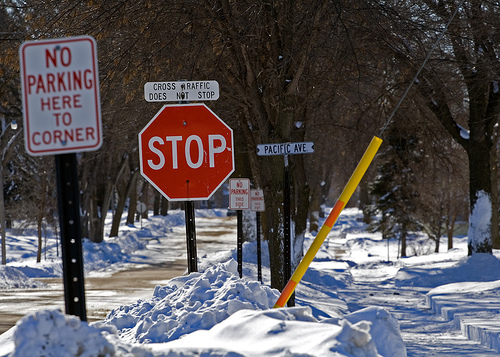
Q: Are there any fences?
A: No, there are no fences.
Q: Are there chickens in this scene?
A: No, there are no chickens.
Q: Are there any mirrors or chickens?
A: No, there are no chickens or mirrors.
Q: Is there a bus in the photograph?
A: No, there are no buses.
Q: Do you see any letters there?
A: Yes, there are letters.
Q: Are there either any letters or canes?
A: Yes, there are letters.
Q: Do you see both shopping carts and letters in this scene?
A: No, there are letters but no shopping carts.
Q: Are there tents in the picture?
A: No, there are no tents.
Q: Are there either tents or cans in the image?
A: No, there are no tents or cans.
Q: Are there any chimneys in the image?
A: No, there are no chimneys.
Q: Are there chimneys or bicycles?
A: No, there are no chimneys or bicycles.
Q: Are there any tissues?
A: No, there are no tissues.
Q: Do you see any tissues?
A: No, there are no tissues.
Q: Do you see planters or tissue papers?
A: No, there are no tissue papers or planters.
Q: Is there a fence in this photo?
A: No, there are no fences.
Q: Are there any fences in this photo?
A: No, there are no fences.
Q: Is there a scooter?
A: No, there are no scooters.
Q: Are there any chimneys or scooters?
A: No, there are no scooters or chimneys.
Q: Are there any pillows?
A: No, there are no pillows.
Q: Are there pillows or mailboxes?
A: No, there are no pillows or mailboxes.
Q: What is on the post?
A: The letter is on the post.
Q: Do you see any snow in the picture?
A: Yes, there is snow.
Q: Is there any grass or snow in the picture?
A: Yes, there is snow.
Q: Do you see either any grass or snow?
A: Yes, there is snow.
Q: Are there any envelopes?
A: No, there are no envelopes.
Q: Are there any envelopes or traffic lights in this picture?
A: No, there are no envelopes or traffic lights.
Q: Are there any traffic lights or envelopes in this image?
A: No, there are no envelopes or traffic lights.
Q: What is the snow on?
A: The snow is on the tree.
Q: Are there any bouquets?
A: No, there are no bouquets.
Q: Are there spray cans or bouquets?
A: No, there are no bouquets or spray cans.